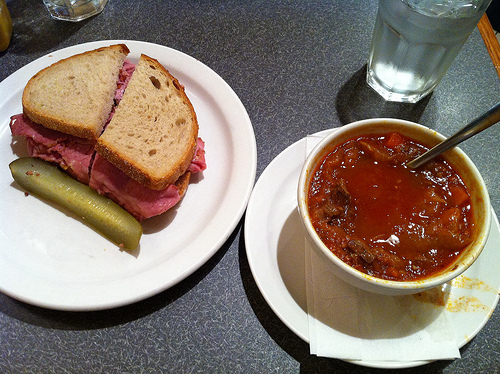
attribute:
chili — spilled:
[446, 276, 484, 307]